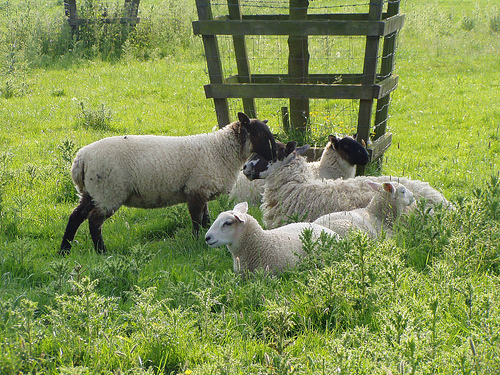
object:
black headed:
[238, 112, 280, 163]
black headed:
[327, 134, 371, 167]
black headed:
[243, 139, 298, 181]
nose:
[365, 149, 372, 165]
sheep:
[311, 181, 417, 243]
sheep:
[226, 134, 372, 206]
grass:
[0, 0, 499, 375]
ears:
[364, 179, 396, 193]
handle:
[100, 145, 226, 188]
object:
[191, 0, 407, 177]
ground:
[0, 0, 499, 373]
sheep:
[60, 111, 279, 256]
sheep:
[241, 141, 457, 230]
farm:
[1, 0, 500, 375]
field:
[0, 0, 497, 373]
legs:
[62, 185, 132, 248]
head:
[204, 201, 248, 248]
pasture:
[1, 0, 500, 375]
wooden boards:
[191, 0, 405, 176]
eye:
[222, 219, 234, 228]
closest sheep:
[204, 201, 341, 278]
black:
[349, 145, 362, 156]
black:
[262, 141, 269, 154]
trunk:
[287, 0, 312, 143]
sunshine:
[2, 0, 499, 374]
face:
[250, 121, 277, 163]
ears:
[231, 201, 248, 225]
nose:
[265, 151, 277, 163]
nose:
[242, 164, 248, 170]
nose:
[410, 193, 416, 201]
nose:
[203, 236, 212, 242]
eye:
[342, 142, 349, 147]